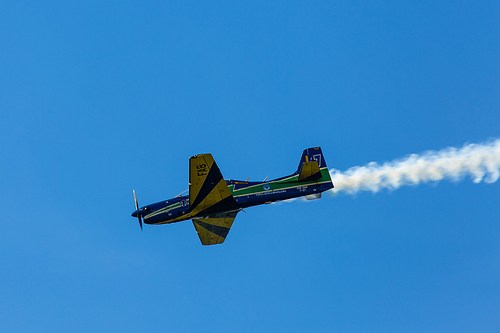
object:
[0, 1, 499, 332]
sky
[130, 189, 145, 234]
propeller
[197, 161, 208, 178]
letters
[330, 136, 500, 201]
smoke trail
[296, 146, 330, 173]
tail fin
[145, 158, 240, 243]
stripe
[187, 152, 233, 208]
wing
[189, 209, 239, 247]
wing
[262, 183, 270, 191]
circle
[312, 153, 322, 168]
7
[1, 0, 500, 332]
day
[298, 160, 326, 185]
tail wing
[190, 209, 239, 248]
right wing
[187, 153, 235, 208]
left wing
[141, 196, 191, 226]
front end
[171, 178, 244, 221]
cockpit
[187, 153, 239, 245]
wing span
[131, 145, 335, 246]
airplane